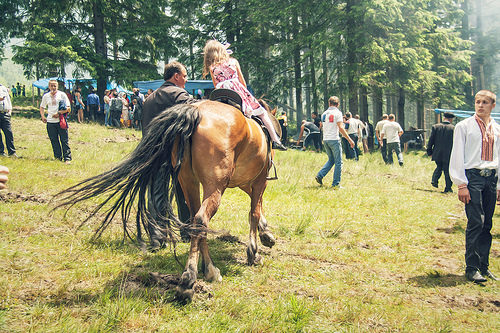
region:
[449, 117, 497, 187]
The luxury of a long sleeved white shirt.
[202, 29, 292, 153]
Blond haired girl rides horse.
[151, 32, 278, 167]
Man escorts girl riding horse.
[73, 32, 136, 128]
A crowd of people under a tree.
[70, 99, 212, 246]
The full and flowing tail of a horse.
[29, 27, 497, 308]
Riding a horse amongst the crowd.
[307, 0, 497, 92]
Trees in the mist.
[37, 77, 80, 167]
A man stands watching.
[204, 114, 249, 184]
The shiney coat of a horse.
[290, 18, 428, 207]
Men head for the event under the trees.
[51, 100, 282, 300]
big brown horse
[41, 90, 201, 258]
large dark hairy tail of horse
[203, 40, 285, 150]
blonde little girl riding a horse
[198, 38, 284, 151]
blonde little girl wearing pink dress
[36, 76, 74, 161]
man wearing white t-shirt and black pants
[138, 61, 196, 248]
man wearing gray t-shirt walking beside horse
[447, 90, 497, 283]
man wearing white and pink t-shirt and blue jeans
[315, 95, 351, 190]
man wearing white t-shirt with bloe white and red flag on it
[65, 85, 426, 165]
a bunch of people sitting next to the trees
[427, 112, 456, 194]
man wearing black jacket and black pants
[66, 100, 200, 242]
one dark fanned out horse tail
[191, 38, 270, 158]
blonde girl riding horse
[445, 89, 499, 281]
man wearing dark pants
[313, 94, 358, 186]
back of man wearing blue jeans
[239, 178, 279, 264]
two front sunlit horse legs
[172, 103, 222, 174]
one light brown sunlit horse behind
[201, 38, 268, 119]
back of girl wearing a pink patterned dress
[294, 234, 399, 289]
floor is green yellow in color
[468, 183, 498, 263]
pants are black in color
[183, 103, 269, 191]
horse is brown in color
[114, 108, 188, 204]
tail is black in color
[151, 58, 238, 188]
man is walking the horse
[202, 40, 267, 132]
young lady sated on a horse back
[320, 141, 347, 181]
pants are faded blue in color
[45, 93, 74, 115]
man is in a white ankara shirt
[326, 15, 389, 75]
trees are green in color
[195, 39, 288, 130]
A little blonde girl riding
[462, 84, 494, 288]
A teenage boy standing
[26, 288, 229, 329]
A grassy field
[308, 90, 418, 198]
A group of men gathering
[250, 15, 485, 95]
A line of tall trees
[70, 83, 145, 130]
A group of men and women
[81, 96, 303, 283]
A brown horse with a black tail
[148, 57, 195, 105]
A man guarding the girl rider..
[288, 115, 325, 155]
A man in black shirt trying to lift something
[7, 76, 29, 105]
Three people in the far back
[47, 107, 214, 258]
a long tail on a horse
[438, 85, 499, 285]
a person is standing up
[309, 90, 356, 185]
a person is standing up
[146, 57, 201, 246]
a person is standing up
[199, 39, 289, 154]
a person is sitting down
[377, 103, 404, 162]
a person is standing up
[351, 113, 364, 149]
a person is standing up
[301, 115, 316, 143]
a person is standing up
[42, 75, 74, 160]
a person is standing up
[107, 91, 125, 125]
a person is standing up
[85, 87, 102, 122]
a person is standing up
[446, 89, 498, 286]
a man in a white and orange shirt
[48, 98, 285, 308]
a brown horse with a black tail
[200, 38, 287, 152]
a girl in a pink dress